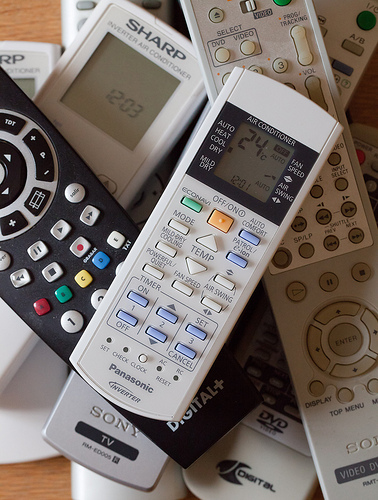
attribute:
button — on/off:
[355, 10, 376, 29]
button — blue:
[239, 228, 260, 244]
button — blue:
[223, 251, 248, 267]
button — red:
[29, 296, 51, 317]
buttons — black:
[0, 106, 63, 240]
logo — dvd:
[252, 403, 295, 435]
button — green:
[179, 194, 197, 207]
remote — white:
[37, 22, 209, 205]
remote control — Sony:
[42, 369, 168, 492]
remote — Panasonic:
[143, 57, 327, 427]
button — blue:
[173, 342, 197, 362]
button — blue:
[183, 320, 210, 339]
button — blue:
[154, 303, 179, 322]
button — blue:
[115, 309, 134, 326]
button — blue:
[142, 324, 170, 341]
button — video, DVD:
[240, 39, 254, 56]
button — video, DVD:
[213, 46, 230, 60]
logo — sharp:
[125, 18, 187, 63]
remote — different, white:
[43, 66, 343, 421]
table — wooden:
[5, 6, 361, 491]